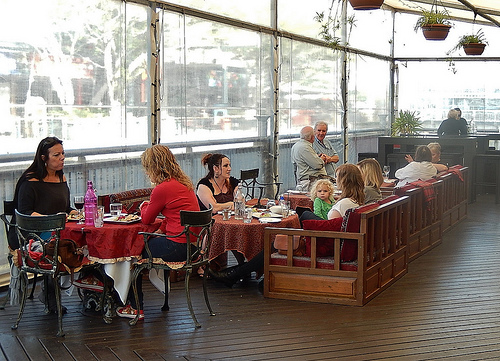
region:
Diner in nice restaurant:
[13, 135, 73, 213]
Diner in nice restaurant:
[129, 143, 200, 262]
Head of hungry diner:
[31, 134, 68, 176]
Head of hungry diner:
[136, 142, 187, 183]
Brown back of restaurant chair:
[176, 205, 218, 270]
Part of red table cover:
[100, 231, 127, 250]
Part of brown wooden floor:
[360, 308, 437, 344]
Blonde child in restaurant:
[305, 178, 335, 213]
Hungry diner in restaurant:
[196, 148, 243, 209]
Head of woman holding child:
[331, 160, 368, 199]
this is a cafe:
[13, 19, 484, 311]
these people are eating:
[86, 131, 384, 324]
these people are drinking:
[40, 101, 395, 306]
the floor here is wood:
[273, 310, 412, 357]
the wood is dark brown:
[251, 307, 325, 329]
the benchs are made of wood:
[250, 165, 442, 359]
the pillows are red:
[302, 207, 413, 289]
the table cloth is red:
[55, 210, 198, 288]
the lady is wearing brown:
[16, 140, 91, 232]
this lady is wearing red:
[131, 172, 236, 290]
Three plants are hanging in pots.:
[319, 0, 490, 54]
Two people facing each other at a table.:
[376, 107, 476, 142]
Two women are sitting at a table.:
[16, 137, 200, 261]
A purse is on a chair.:
[10, 209, 84, 336]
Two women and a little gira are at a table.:
[195, 153, 365, 222]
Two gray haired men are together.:
[292, 120, 339, 175]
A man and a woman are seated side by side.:
[394, 142, 455, 180]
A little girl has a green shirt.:
[306, 180, 337, 217]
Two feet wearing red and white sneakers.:
[69, 275, 146, 322]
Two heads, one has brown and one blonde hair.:
[333, 157, 384, 204]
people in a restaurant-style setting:
[0, 0, 498, 338]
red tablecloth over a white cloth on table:
[55, 216, 164, 305]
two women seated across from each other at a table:
[0, 136, 213, 330]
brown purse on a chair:
[9, 207, 85, 337]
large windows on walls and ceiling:
[0, 1, 497, 172]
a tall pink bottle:
[81, 180, 97, 230]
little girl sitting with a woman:
[295, 165, 360, 225]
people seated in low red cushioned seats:
[260, 140, 465, 305]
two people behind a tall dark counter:
[377, 106, 487, 200]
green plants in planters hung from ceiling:
[313, 1, 490, 76]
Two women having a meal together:
[9, 133, 201, 322]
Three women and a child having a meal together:
[195, 150, 384, 219]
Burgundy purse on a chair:
[42, 238, 84, 272]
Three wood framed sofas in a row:
[260, 163, 471, 307]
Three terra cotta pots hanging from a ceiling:
[345, 0, 487, 56]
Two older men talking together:
[289, 120, 341, 178]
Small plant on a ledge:
[389, 108, 424, 137]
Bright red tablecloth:
[53, 216, 163, 258]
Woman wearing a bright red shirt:
[137, 143, 204, 243]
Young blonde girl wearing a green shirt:
[310, 177, 335, 217]